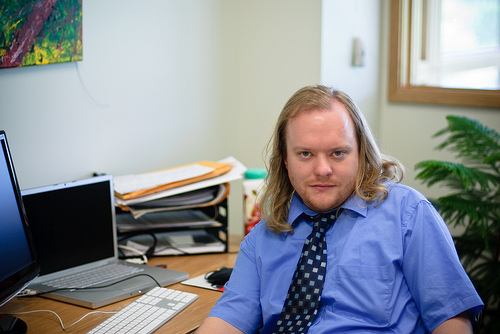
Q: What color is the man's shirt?
A: Blue.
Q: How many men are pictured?
A: One.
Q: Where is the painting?
A: Hanging on the wall.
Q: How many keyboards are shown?
A: Two.